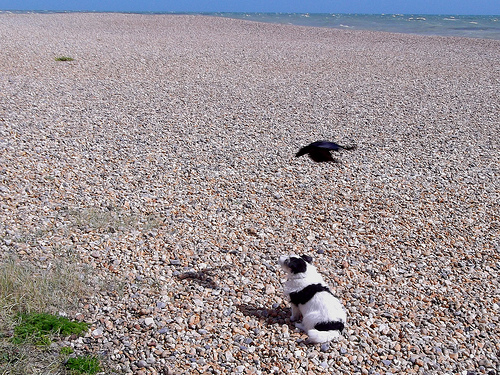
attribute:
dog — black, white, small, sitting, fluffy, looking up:
[278, 253, 348, 344]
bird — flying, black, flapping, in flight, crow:
[296, 138, 357, 164]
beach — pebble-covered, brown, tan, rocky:
[0, 9, 500, 374]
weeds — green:
[0, 262, 123, 375]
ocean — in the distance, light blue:
[0, 7, 499, 38]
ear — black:
[289, 256, 307, 272]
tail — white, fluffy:
[306, 326, 340, 344]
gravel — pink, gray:
[1, 13, 500, 374]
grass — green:
[13, 310, 92, 346]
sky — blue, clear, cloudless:
[0, 0, 500, 15]